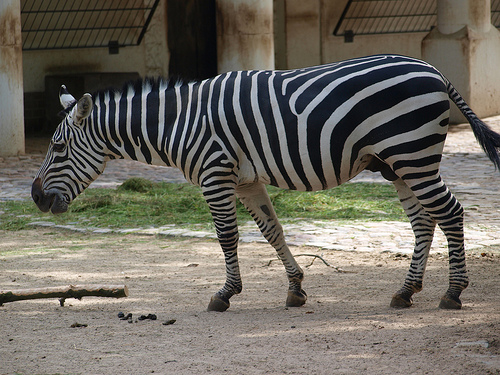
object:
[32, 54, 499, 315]
zebra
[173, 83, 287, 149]
stripes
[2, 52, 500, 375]
area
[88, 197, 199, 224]
grass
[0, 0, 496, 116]
wall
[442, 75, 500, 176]
tail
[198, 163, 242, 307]
leg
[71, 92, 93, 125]
ear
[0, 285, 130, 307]
branch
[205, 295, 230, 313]
hoof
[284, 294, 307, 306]
hoof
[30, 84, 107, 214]
head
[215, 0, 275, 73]
cloumn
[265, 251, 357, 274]
twig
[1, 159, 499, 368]
ground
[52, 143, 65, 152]
eye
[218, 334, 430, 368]
sand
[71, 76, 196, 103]
hair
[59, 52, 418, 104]
zebra's back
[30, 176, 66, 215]
mouth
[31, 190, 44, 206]
nose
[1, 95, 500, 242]
field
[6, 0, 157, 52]
rail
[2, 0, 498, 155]
building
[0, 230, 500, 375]
dirt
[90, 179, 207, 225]
patch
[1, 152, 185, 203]
walkway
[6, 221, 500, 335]
road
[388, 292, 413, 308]
hoof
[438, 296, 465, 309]
hoof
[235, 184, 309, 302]
leg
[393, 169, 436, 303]
leg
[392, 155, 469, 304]
leg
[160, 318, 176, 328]
rocks